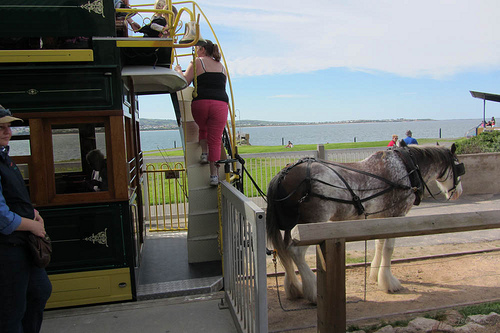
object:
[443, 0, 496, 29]
clouds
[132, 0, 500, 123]
sky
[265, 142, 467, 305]
horse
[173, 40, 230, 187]
woman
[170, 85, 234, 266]
stairs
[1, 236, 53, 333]
pants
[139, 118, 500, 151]
water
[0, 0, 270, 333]
building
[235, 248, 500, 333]
dirt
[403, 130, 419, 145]
people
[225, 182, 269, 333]
fence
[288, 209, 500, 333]
fence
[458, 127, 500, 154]
bushes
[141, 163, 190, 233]
gate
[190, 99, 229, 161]
pants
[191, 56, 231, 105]
shirt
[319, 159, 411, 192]
straps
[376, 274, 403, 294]
feet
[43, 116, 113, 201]
window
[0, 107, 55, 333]
person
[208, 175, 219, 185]
shoes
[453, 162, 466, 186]
blinders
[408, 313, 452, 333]
stones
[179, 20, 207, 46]
bell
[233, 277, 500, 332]
shadoow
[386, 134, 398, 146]
people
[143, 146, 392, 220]
rail